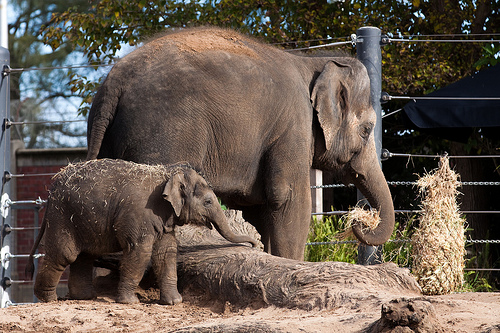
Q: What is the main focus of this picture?
A: Elephants.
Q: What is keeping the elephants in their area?
A: A fence.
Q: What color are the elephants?
A: Brown.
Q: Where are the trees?
A: Outside fence.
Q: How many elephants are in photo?
A: Two.